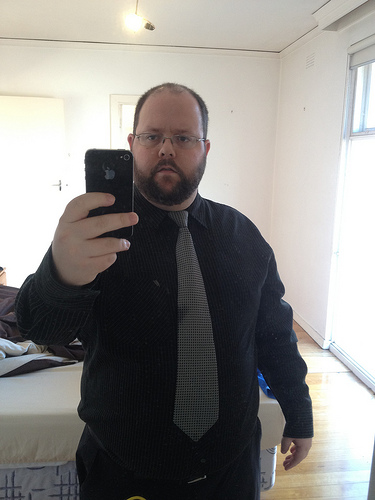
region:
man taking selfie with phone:
[14, 79, 316, 498]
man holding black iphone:
[82, 145, 135, 243]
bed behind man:
[2, 263, 285, 496]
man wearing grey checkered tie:
[172, 205, 221, 446]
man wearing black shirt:
[14, 182, 331, 454]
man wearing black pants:
[73, 421, 264, 498]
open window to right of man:
[342, 36, 374, 137]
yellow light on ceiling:
[119, 5, 150, 36]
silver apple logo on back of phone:
[101, 166, 119, 184]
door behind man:
[105, 92, 147, 154]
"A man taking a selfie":
[4, 67, 255, 315]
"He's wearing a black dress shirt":
[12, 81, 323, 471]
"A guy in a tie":
[12, 68, 322, 463]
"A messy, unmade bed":
[0, 274, 105, 496]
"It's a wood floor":
[272, 322, 373, 497]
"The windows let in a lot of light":
[0, 60, 374, 409]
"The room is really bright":
[0, 45, 372, 347]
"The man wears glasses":
[127, 71, 219, 211]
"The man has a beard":
[111, 64, 239, 213]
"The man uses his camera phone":
[55, 74, 242, 280]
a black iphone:
[76, 145, 139, 243]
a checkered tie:
[165, 209, 223, 445]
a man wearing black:
[13, 65, 332, 425]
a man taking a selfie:
[45, 63, 245, 255]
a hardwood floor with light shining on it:
[313, 363, 373, 494]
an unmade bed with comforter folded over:
[0, 337, 75, 460]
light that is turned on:
[87, 2, 198, 40]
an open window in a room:
[336, 42, 372, 120]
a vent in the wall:
[287, 49, 332, 67]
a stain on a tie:
[157, 292, 202, 329]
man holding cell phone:
[13, 78, 334, 485]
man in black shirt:
[11, 79, 339, 496]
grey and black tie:
[164, 212, 230, 443]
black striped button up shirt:
[28, 173, 315, 467]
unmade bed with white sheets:
[0, 286, 272, 481]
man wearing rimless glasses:
[117, 75, 214, 211]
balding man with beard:
[28, 77, 327, 480]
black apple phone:
[84, 143, 140, 239]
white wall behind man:
[5, 43, 282, 281]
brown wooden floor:
[272, 328, 369, 492]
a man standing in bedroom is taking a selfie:
[11, 5, 354, 489]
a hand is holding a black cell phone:
[53, 145, 137, 284]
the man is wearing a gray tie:
[38, 72, 297, 489]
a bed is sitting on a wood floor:
[0, 440, 70, 498]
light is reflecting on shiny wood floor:
[332, 380, 362, 449]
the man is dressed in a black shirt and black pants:
[36, 81, 295, 489]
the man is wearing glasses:
[118, 76, 233, 215]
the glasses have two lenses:
[135, 127, 203, 151]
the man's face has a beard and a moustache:
[134, 84, 209, 208]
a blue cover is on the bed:
[259, 378, 275, 388]